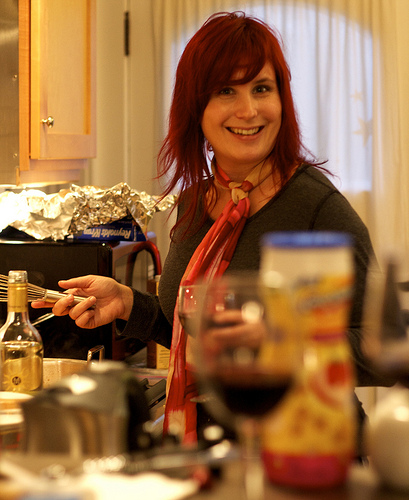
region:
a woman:
[89, 73, 376, 496]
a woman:
[125, 154, 315, 460]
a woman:
[213, 115, 312, 352]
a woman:
[184, 9, 346, 362]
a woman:
[169, 197, 265, 455]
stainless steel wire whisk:
[1, 267, 96, 315]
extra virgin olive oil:
[0, 261, 47, 428]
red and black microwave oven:
[0, 228, 162, 361]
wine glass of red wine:
[191, 266, 310, 495]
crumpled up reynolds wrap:
[29, 179, 169, 240]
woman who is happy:
[157, 7, 343, 234]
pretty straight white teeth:
[211, 117, 272, 137]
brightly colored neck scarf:
[214, 178, 246, 265]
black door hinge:
[113, 7, 134, 59]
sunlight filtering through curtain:
[293, 22, 399, 203]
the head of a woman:
[169, 5, 293, 169]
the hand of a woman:
[25, 267, 136, 329]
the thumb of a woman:
[55, 271, 98, 290]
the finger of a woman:
[66, 292, 100, 321]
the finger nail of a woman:
[88, 293, 97, 303]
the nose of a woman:
[232, 88, 257, 124]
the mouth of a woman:
[220, 115, 274, 140]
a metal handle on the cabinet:
[38, 111, 61, 130]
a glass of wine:
[189, 264, 302, 498]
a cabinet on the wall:
[24, 1, 104, 161]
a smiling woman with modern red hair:
[155, 10, 327, 202]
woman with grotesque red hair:
[134, 7, 331, 218]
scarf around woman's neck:
[159, 140, 291, 497]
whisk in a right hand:
[0, 271, 139, 331]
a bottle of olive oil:
[0, 260, 46, 393]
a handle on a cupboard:
[33, 110, 65, 131]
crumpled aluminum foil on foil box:
[1, 178, 177, 252]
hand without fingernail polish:
[22, 263, 131, 334]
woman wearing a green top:
[63, 22, 389, 427]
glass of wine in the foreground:
[178, 270, 318, 499]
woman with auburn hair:
[57, 12, 384, 489]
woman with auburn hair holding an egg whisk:
[42, 4, 404, 439]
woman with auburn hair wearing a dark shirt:
[18, 7, 384, 411]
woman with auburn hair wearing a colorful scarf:
[58, 14, 389, 401]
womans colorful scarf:
[161, 150, 312, 444]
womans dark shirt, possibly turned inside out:
[106, 161, 403, 418]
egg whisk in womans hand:
[2, 270, 99, 314]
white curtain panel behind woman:
[154, 0, 387, 240]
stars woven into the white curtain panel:
[346, 86, 382, 147]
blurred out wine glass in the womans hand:
[169, 275, 240, 410]